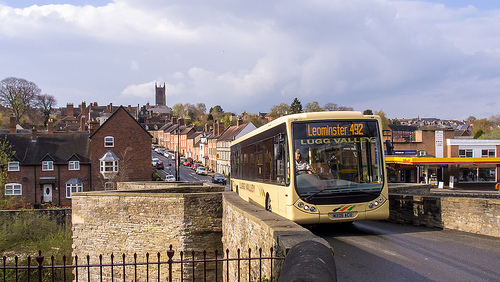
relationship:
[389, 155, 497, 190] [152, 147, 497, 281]
station by road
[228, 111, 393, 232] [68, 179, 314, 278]
bus on bridge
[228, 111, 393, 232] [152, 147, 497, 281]
bus on road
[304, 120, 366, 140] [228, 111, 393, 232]
placard on bus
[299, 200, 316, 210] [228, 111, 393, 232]
light on bus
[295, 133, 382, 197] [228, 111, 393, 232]
windshield on bus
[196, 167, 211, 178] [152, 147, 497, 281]
car on road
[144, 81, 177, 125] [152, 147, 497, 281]
church by road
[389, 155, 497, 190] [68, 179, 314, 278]
station by bridge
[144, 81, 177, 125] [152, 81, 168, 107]
church has a steeple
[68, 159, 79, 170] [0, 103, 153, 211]
window on building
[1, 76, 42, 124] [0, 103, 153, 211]
tree by building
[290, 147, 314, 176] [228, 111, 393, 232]
man driving bus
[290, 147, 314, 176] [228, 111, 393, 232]
man on bus